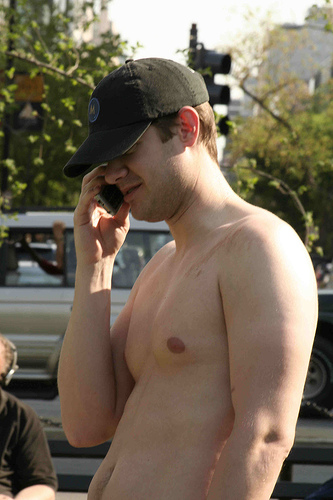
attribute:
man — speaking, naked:
[62, 57, 321, 498]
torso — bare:
[139, 267, 238, 460]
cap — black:
[88, 72, 195, 116]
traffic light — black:
[185, 25, 235, 67]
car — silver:
[6, 222, 58, 347]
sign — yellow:
[13, 69, 50, 135]